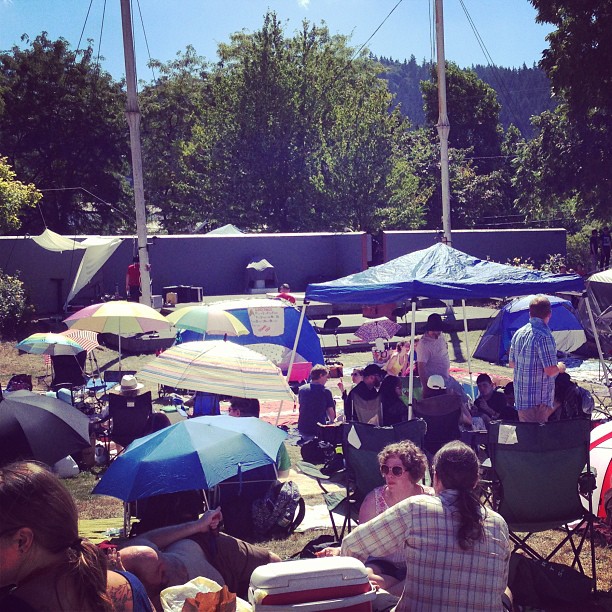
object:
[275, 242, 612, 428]
canopy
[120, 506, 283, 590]
person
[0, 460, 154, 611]
person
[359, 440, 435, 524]
person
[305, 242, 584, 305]
canopy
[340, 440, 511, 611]
man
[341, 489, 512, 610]
plaid shirt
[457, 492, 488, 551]
ponytail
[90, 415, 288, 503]
blue umbrella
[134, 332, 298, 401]
striped umbrella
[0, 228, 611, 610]
park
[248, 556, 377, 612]
cooler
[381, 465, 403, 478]
black sunglasses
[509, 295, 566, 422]
man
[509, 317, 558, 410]
plaid shirt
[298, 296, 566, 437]
people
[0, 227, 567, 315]
blue fence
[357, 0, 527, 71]
sky